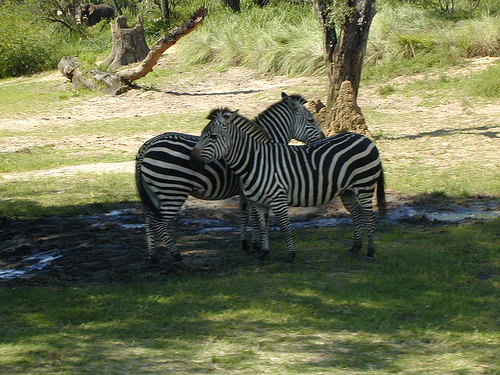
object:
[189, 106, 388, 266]
zebra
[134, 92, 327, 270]
zebra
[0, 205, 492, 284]
water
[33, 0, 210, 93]
tree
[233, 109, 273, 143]
mane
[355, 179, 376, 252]
leg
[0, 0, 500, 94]
grass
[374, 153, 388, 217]
tail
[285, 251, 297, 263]
hoof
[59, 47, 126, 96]
branch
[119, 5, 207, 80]
stump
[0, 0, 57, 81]
plant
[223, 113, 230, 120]
ear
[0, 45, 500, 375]
field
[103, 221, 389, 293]
trail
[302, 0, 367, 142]
tree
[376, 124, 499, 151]
shadow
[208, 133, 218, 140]
eye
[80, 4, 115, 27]
elephant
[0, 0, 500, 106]
background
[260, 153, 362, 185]
stripes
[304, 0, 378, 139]
tree trunk